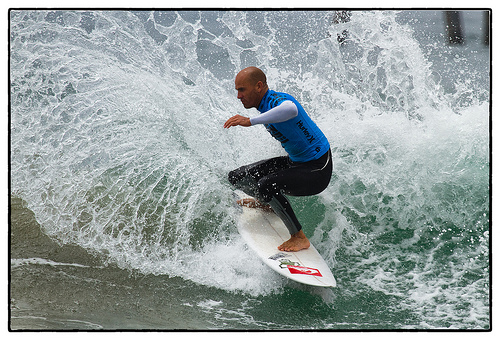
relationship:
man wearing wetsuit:
[223, 66, 332, 253] [229, 89, 331, 234]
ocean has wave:
[11, 8, 490, 330] [8, 36, 489, 307]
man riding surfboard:
[223, 66, 332, 253] [227, 187, 337, 288]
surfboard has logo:
[227, 187, 337, 288] [287, 263, 322, 277]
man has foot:
[223, 66, 332, 253] [277, 234, 309, 251]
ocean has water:
[11, 8, 490, 330] [11, 194, 213, 331]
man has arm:
[223, 66, 332, 253] [223, 99, 299, 127]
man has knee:
[223, 66, 332, 253] [257, 175, 274, 196]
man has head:
[223, 66, 332, 253] [235, 66, 268, 109]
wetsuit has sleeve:
[229, 89, 331, 234] [249, 101, 300, 128]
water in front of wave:
[11, 194, 213, 331] [8, 36, 489, 307]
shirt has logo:
[256, 89, 329, 162] [295, 118, 317, 144]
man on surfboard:
[223, 66, 332, 253] [227, 187, 337, 288]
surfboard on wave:
[227, 187, 337, 288] [8, 36, 489, 307]